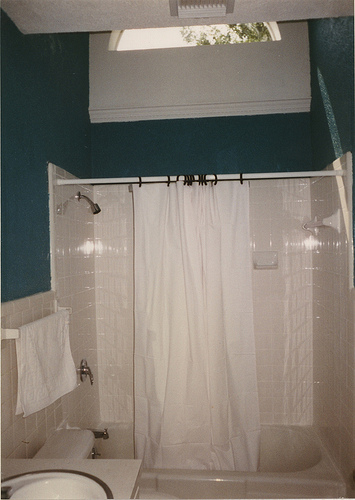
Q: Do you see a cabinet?
A: No, there are no cabinets.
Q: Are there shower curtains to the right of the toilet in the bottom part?
A: Yes, there is a shower curtain to the right of the toilet.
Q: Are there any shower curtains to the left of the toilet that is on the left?
A: No, the shower curtain is to the right of the toilet.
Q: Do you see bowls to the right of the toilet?
A: No, there is a shower curtain to the right of the toilet.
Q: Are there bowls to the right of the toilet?
A: No, there is a shower curtain to the right of the toilet.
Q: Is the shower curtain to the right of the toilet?
A: Yes, the shower curtain is to the right of the toilet.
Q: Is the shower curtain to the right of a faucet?
A: No, the shower curtain is to the right of the toilet.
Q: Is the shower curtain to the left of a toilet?
A: No, the shower curtain is to the right of a toilet.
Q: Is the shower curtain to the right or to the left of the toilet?
A: The shower curtain is to the right of the toilet.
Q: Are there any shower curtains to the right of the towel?
A: Yes, there is a shower curtain to the right of the towel.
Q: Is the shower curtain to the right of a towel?
A: Yes, the shower curtain is to the right of a towel.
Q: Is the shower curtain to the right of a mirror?
A: No, the shower curtain is to the right of a towel.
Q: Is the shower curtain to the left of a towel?
A: No, the shower curtain is to the right of a towel.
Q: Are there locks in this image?
A: No, there are no locks.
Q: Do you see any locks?
A: No, there are no locks.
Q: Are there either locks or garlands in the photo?
A: No, there are no locks or garlands.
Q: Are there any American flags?
A: No, there are no American flags.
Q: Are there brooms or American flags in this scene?
A: No, there are no American flags or brooms.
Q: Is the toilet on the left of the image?
A: Yes, the toilet is on the left of the image.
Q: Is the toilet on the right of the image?
A: No, the toilet is on the left of the image.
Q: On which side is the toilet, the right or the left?
A: The toilet is on the left of the image.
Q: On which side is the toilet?
A: The toilet is on the left of the image.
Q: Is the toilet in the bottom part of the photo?
A: Yes, the toilet is in the bottom of the image.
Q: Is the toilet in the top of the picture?
A: No, the toilet is in the bottom of the image.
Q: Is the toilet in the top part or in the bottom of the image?
A: The toilet is in the bottom of the image.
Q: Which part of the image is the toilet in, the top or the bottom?
A: The toilet is in the bottom of the image.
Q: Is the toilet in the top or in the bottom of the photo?
A: The toilet is in the bottom of the image.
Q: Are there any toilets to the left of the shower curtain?
A: Yes, there is a toilet to the left of the shower curtain.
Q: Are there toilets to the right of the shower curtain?
A: No, the toilet is to the left of the shower curtain.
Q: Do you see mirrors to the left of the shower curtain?
A: No, there is a toilet to the left of the shower curtain.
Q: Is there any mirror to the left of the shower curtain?
A: No, there is a toilet to the left of the shower curtain.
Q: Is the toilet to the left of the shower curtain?
A: Yes, the toilet is to the left of the shower curtain.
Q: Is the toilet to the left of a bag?
A: No, the toilet is to the left of the shower curtain.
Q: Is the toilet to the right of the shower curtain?
A: No, the toilet is to the left of the shower curtain.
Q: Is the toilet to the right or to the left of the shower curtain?
A: The toilet is to the left of the shower curtain.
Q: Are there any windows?
A: Yes, there is a window.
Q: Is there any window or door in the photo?
A: Yes, there is a window.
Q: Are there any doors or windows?
A: Yes, there is a window.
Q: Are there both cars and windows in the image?
A: No, there is a window but no cars.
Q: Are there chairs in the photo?
A: No, there are no chairs.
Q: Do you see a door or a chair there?
A: No, there are no chairs or doors.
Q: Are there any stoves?
A: No, there are no stoves.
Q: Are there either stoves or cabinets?
A: No, there are no stoves or cabinets.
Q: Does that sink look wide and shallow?
A: Yes, the sink is wide and shallow.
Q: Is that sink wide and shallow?
A: Yes, the sink is wide and shallow.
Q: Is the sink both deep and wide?
A: No, the sink is wide but shallow.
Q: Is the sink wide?
A: Yes, the sink is wide.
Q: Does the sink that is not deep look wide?
A: Yes, the sink is wide.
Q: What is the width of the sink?
A: The sink is wide.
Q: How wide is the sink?
A: The sink is wide.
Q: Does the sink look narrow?
A: No, the sink is wide.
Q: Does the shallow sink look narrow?
A: No, the sink is wide.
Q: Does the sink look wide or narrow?
A: The sink is wide.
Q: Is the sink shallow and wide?
A: Yes, the sink is shallow and wide.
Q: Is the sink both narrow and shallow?
A: No, the sink is shallow but wide.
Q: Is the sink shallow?
A: Yes, the sink is shallow.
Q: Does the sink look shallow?
A: Yes, the sink is shallow.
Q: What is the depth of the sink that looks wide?
A: The sink is shallow.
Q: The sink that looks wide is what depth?
A: The sink is shallow.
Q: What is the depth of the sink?
A: The sink is shallow.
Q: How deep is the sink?
A: The sink is shallow.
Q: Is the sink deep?
A: No, the sink is shallow.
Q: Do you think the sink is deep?
A: No, the sink is shallow.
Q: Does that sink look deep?
A: No, the sink is shallow.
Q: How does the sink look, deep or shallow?
A: The sink is shallow.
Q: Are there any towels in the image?
A: Yes, there is a towel.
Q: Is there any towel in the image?
A: Yes, there is a towel.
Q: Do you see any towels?
A: Yes, there is a towel.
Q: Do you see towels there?
A: Yes, there is a towel.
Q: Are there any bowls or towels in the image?
A: Yes, there is a towel.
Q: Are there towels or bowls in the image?
A: Yes, there is a towel.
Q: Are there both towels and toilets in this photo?
A: Yes, there are both a towel and a toilet.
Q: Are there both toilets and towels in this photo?
A: Yes, there are both a towel and a toilet.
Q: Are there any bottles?
A: No, there are no bottles.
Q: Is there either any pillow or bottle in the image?
A: No, there are no bottles or pillows.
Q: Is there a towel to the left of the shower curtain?
A: Yes, there is a towel to the left of the shower curtain.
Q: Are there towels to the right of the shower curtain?
A: No, the towel is to the left of the shower curtain.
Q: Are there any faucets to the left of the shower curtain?
A: No, there is a towel to the left of the shower curtain.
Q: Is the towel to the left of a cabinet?
A: No, the towel is to the left of the shower curtain.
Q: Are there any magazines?
A: No, there are no magazines.